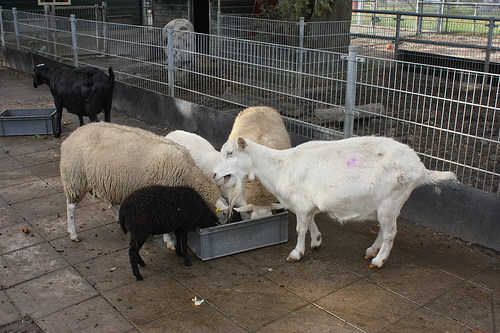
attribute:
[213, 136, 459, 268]
goat — white, eating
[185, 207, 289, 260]
container — small, silver, gray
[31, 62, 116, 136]
goat — shiny, black, standing, small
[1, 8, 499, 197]
fence — metal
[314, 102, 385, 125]
log — brown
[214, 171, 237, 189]
mouth — open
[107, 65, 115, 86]
tail — black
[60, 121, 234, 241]
goat — brown, grey, eating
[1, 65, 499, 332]
floor — brown, dirty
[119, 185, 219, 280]
goat — small, black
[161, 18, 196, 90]
cow — here, spotted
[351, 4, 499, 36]
area — grassy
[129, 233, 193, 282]
legs — black